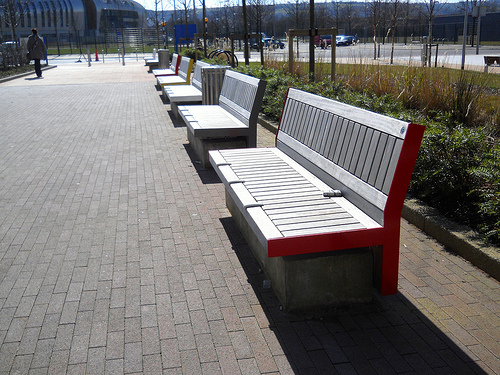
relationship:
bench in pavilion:
[206, 87, 425, 311] [3, 59, 483, 371]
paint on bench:
[387, 205, 398, 248] [208, 87, 426, 305]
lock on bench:
[323, 190, 342, 197] [208, 87, 426, 305]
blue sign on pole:
[170, 20, 209, 50] [177, 31, 194, 53]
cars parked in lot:
[282, 19, 377, 58] [232, 39, 482, 59]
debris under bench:
[230, 251, 297, 317] [208, 87, 426, 305]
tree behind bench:
[306, 3, 324, 88] [192, 87, 432, 314]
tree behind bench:
[456, 6, 475, 71] [173, 67, 267, 159]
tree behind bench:
[417, 2, 442, 81] [162, 57, 213, 112]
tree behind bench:
[236, 1, 256, 68] [158, 54, 193, 94]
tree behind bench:
[149, 5, 170, 47] [151, 52, 182, 84]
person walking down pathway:
[24, 22, 48, 77] [1, 65, 498, 374]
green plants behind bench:
[396, 120, 498, 237] [152, 53, 181, 78]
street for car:
[208, 14, 448, 79] [242, 32, 285, 49]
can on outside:
[183, 46, 220, 101] [0, 0, 500, 375]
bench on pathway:
[175, 89, 472, 281] [1, 27, 500, 375]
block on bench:
[212, 181, 374, 324] [200, 79, 438, 300]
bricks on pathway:
[153, 293, 175, 340] [1, 65, 498, 374]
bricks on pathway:
[176, 324, 198, 351] [1, 65, 498, 374]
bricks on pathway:
[184, 290, 201, 310] [1, 65, 498, 374]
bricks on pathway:
[108, 306, 125, 331] [1, 65, 498, 374]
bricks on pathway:
[124, 341, 142, 372] [1, 65, 498, 374]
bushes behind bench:
[172, 46, 499, 245] [208, 87, 426, 305]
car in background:
[243, 27, 288, 53] [212, 12, 315, 51]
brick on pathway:
[99, 136, 105, 146] [1, 27, 500, 375]